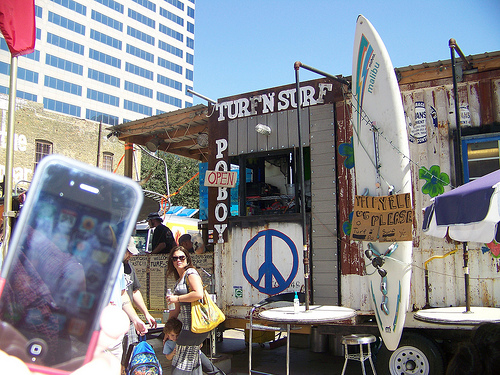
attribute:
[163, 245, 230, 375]
woman — young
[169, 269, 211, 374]
dress — grey, white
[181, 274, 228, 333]
purse — yellow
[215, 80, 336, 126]
sign — turf n surf, black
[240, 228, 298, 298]
peace symbol — blue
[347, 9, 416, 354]
surfboard — white, green, hanging, blue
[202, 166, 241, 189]
sign — open, white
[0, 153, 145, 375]
iphone — being held, with reflection, in foreground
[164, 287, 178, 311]
bottle — plastic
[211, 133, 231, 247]
sign — poboy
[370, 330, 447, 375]
tire — car tire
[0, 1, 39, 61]
flag — red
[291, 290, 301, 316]
bottle — blue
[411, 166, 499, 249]
umbrella — blue, purple, white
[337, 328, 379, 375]
stool — silver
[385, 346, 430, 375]
rim — white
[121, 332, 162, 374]
backpack — blue